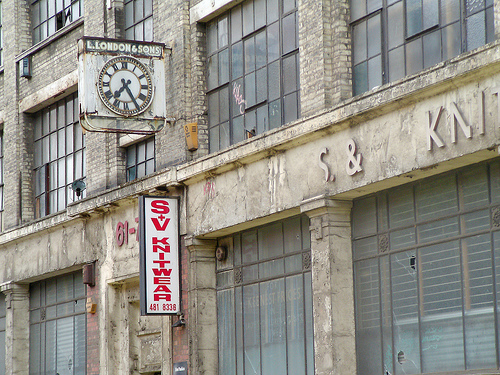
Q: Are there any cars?
A: No, there are no cars.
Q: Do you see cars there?
A: No, there are no cars.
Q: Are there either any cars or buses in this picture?
A: No, there are no cars or buses.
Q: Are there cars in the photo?
A: No, there are no cars.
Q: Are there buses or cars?
A: No, there are no cars or buses.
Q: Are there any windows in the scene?
A: Yes, there are windows.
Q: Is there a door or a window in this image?
A: Yes, there are windows.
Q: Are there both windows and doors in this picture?
A: No, there are windows but no doors.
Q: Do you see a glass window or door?
A: Yes, there are glass windows.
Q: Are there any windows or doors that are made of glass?
A: Yes, the windows are made of glass.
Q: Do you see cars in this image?
A: No, there are no cars.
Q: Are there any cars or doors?
A: No, there are no cars or doors.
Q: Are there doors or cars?
A: No, there are no cars or doors.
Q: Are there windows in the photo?
A: Yes, there are windows.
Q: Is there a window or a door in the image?
A: Yes, there are windows.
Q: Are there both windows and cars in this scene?
A: No, there are windows but no cars.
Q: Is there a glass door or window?
A: Yes, there are glass windows.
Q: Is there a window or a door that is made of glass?
A: Yes, the windows are made of glass.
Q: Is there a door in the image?
A: No, there are no doors.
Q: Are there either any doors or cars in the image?
A: No, there are no doors or cars.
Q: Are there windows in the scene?
A: Yes, there is a window.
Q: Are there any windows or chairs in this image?
A: Yes, there is a window.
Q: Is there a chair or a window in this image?
A: Yes, there is a window.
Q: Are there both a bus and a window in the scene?
A: No, there is a window but no buses.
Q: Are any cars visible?
A: No, there are no cars.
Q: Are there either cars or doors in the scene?
A: No, there are no cars or doors.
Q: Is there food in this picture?
A: No, there is no food.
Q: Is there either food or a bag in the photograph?
A: No, there are no food or bags.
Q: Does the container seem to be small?
A: Yes, the container is small.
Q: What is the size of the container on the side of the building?
A: The container is small.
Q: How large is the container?
A: The container is small.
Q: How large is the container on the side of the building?
A: The container is small.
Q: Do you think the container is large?
A: No, the container is small.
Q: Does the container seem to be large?
A: No, the container is small.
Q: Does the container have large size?
A: No, the container is small.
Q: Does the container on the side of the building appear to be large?
A: No, the container is small.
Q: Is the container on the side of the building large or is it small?
A: The container is small.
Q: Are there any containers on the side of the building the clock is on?
A: Yes, there is a container on the side of the building.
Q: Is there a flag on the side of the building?
A: No, there is a container on the side of the building.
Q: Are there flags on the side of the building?
A: No, there is a container on the side of the building.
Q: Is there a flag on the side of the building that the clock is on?
A: No, there is a container on the side of the building.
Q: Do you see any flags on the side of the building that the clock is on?
A: No, there is a container on the side of the building.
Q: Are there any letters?
A: Yes, there are letters.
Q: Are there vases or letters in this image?
A: Yes, there are letters.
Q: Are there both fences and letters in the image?
A: No, there are letters but no fences.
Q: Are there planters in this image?
A: No, there are no planters.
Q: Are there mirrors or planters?
A: No, there are no planters or mirrors.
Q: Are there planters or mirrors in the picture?
A: No, there are no planters or mirrors.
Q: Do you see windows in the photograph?
A: Yes, there is a window.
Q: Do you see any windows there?
A: Yes, there is a window.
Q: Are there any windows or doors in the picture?
A: Yes, there is a window.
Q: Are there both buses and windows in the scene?
A: No, there is a window but no buses.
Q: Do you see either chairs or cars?
A: No, there are no cars or chairs.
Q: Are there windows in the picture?
A: Yes, there is a window.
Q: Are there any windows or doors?
A: Yes, there is a window.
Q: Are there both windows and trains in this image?
A: No, there is a window but no trains.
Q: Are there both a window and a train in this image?
A: No, there is a window but no trains.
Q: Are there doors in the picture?
A: No, there are no doors.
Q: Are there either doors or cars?
A: No, there are no doors or cars.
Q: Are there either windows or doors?
A: Yes, there is a window.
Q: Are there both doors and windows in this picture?
A: No, there is a window but no doors.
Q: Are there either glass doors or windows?
A: Yes, there is a glass window.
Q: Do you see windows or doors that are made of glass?
A: Yes, the window is made of glass.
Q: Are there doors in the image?
A: No, there are no doors.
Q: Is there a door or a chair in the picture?
A: No, there are no doors or chairs.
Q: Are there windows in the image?
A: Yes, there is a window.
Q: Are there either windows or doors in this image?
A: Yes, there is a window.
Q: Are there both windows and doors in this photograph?
A: No, there is a window but no doors.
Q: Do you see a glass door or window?
A: Yes, there is a glass window.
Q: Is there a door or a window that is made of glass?
A: Yes, the window is made of glass.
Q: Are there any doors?
A: No, there are no doors.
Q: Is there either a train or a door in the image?
A: No, there are no doors or trains.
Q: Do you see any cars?
A: No, there are no cars.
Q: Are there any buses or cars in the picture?
A: No, there are no cars or buses.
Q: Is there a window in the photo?
A: Yes, there is a window.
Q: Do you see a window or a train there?
A: Yes, there is a window.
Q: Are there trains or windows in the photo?
A: Yes, there is a window.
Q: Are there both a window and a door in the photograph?
A: No, there is a window but no doors.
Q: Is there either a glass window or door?
A: Yes, there is a glass window.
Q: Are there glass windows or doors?
A: Yes, there is a glass window.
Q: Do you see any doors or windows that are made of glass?
A: Yes, the window is made of glass.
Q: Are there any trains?
A: No, there are no trains.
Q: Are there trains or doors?
A: No, there are no trains or doors.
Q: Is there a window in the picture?
A: Yes, there is a window.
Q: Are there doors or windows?
A: Yes, there is a window.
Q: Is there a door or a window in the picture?
A: Yes, there is a window.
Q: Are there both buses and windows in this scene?
A: No, there is a window but no buses.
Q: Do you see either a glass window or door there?
A: Yes, there is a glass window.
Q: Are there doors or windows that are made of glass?
A: Yes, the window is made of glass.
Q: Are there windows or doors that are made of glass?
A: Yes, the window is made of glass.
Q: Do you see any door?
A: No, there are no doors.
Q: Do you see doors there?
A: No, there are no doors.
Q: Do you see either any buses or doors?
A: No, there are no doors or buses.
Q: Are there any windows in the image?
A: Yes, there is a window.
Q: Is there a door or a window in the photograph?
A: Yes, there is a window.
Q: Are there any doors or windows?
A: Yes, there is a window.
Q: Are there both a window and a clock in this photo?
A: Yes, there are both a window and a clock.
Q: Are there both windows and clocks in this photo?
A: Yes, there are both a window and a clock.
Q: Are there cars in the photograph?
A: No, there are no cars.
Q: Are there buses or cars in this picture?
A: No, there are no cars or buses.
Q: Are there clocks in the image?
A: Yes, there is a clock.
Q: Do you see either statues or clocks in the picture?
A: Yes, there is a clock.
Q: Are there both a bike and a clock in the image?
A: No, there is a clock but no bikes.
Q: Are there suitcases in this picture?
A: No, there are no suitcases.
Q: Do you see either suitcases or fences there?
A: No, there are no suitcases or fences.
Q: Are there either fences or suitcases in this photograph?
A: No, there are no suitcases or fences.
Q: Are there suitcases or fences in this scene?
A: No, there are no suitcases or fences.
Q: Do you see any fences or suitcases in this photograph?
A: No, there are no suitcases or fences.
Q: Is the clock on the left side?
A: Yes, the clock is on the left of the image.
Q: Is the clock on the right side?
A: No, the clock is on the left of the image.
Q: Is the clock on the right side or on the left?
A: The clock is on the left of the image.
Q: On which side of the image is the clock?
A: The clock is on the left of the image.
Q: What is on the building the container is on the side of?
A: The clock is on the building.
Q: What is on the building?
A: The clock is on the building.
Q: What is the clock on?
A: The clock is on the building.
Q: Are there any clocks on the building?
A: Yes, there is a clock on the building.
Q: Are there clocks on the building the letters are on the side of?
A: Yes, there is a clock on the building.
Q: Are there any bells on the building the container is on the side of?
A: No, there is a clock on the building.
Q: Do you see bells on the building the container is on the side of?
A: No, there is a clock on the building.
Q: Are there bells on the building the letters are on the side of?
A: No, there is a clock on the building.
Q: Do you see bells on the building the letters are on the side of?
A: No, there is a clock on the building.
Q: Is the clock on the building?
A: Yes, the clock is on the building.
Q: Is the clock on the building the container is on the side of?
A: Yes, the clock is on the building.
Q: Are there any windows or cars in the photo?
A: Yes, there is a window.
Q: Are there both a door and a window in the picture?
A: No, there is a window but no doors.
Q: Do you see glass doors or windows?
A: Yes, there is a glass window.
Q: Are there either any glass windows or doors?
A: Yes, there is a glass window.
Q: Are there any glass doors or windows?
A: Yes, there is a glass window.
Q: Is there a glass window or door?
A: Yes, there is a glass window.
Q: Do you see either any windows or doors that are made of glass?
A: Yes, the window is made of glass.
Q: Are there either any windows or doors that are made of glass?
A: Yes, the window is made of glass.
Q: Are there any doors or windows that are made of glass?
A: Yes, the window is made of glass.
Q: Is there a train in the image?
A: No, there are no trains.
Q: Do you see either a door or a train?
A: No, there are no trains or doors.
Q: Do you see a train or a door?
A: No, there are no trains or doors.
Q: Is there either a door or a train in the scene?
A: No, there are no trains or doors.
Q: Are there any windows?
A: Yes, there is a window.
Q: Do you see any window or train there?
A: Yes, there is a window.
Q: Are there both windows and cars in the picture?
A: No, there is a window but no cars.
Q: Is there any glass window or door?
A: Yes, there is a glass window.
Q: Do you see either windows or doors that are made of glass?
A: Yes, the window is made of glass.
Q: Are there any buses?
A: No, there are no buses.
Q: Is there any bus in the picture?
A: No, there are no buses.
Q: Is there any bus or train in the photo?
A: No, there are no buses or trains.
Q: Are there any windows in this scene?
A: Yes, there is a window.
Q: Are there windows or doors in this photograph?
A: Yes, there is a window.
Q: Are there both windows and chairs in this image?
A: No, there is a window but no chairs.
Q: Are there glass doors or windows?
A: Yes, there is a glass window.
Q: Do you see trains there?
A: No, there are no trains.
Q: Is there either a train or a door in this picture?
A: No, there are no trains or doors.